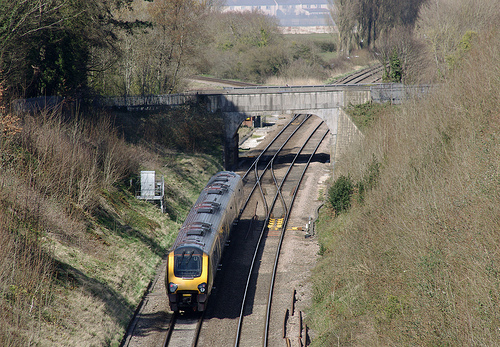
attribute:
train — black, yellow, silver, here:
[164, 171, 246, 315]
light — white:
[200, 286, 206, 293]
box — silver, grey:
[140, 170, 156, 197]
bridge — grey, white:
[23, 86, 441, 172]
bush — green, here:
[328, 176, 351, 214]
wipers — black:
[178, 252, 194, 267]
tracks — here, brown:
[119, 59, 389, 346]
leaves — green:
[109, 17, 156, 34]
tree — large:
[0, 1, 156, 98]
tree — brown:
[166, 0, 207, 94]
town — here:
[205, 0, 333, 34]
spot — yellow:
[268, 216, 283, 230]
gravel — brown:
[118, 58, 399, 347]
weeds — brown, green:
[0, 113, 222, 346]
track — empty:
[235, 66, 392, 346]